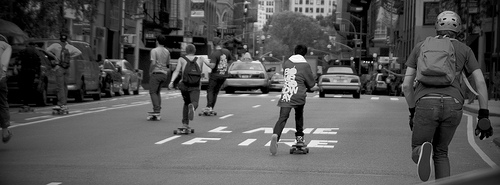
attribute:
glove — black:
[399, 103, 418, 123]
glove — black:
[473, 109, 494, 141]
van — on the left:
[45, 28, 125, 100]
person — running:
[394, 20, 484, 167]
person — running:
[197, 34, 237, 124]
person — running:
[170, 35, 210, 132]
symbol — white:
[277, 55, 305, 103]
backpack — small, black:
[48, 40, 98, 88]